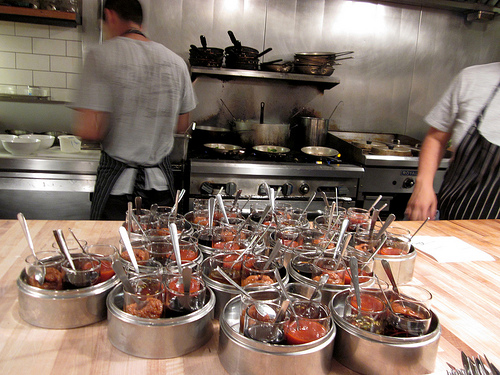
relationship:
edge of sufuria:
[97, 183, 98, 185] [220, 282, 452, 371]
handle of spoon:
[268, 263, 291, 295] [291, 304, 301, 321]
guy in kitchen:
[65, 0, 200, 221] [1, 0, 498, 372]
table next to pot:
[369, 220, 499, 367] [332, 287, 437, 373]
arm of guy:
[404, 126, 446, 219] [65, 0, 200, 221]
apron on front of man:
[422, 73, 487, 130] [435, 84, 486, 145]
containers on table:
[16, 200, 442, 375] [3, 219, 497, 370]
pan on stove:
[301, 146, 340, 157] [185, 116, 363, 218]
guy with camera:
[65, 0, 200, 221] [2, 0, 498, 374]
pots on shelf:
[184, 27, 358, 80] [188, 65, 343, 97]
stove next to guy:
[196, 128, 362, 192] [65, 0, 200, 221]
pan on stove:
[293, 144, 352, 172] [184, 125, 369, 222]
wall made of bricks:
[2, 22, 79, 91] [5, 35, 71, 59]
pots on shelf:
[188, 30, 355, 77] [186, 64, 338, 88]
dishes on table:
[35, 141, 499, 369] [11, 200, 497, 375]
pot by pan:
[292, 108, 332, 145] [301, 146, 340, 157]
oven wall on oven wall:
[98, 0, 499, 142] [78, 0, 493, 151]